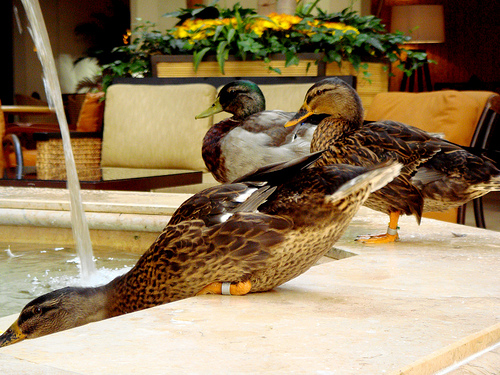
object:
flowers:
[321, 21, 332, 29]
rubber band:
[219, 280, 231, 296]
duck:
[282, 77, 499, 246]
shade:
[389, 4, 446, 45]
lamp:
[390, 6, 447, 95]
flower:
[178, 28, 188, 38]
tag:
[386, 229, 398, 235]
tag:
[222, 283, 230, 294]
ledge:
[0, 198, 178, 215]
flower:
[332, 32, 335, 36]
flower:
[280, 21, 293, 32]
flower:
[281, 20, 291, 29]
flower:
[248, 27, 261, 39]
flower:
[196, 18, 201, 23]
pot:
[144, 52, 393, 95]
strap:
[388, 229, 397, 235]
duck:
[192, 79, 318, 184]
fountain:
[16, 0, 99, 291]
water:
[0, 240, 146, 319]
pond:
[0, 200, 355, 345]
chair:
[365, 90, 499, 227]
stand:
[11, 132, 24, 180]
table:
[0, 104, 50, 115]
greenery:
[192, 46, 210, 74]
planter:
[242, 0, 437, 88]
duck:
[0, 148, 404, 344]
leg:
[205, 282, 251, 295]